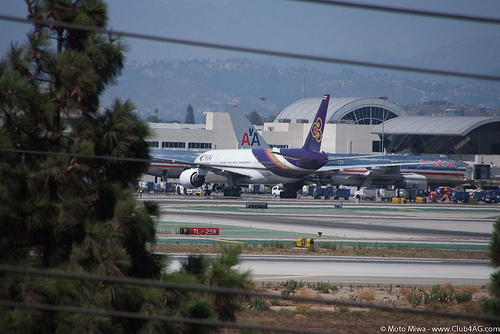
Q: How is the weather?
A: It is clear.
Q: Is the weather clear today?
A: Yes, it is clear.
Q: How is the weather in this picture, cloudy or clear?
A: It is clear.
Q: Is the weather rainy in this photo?
A: No, it is clear.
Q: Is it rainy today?
A: No, it is clear.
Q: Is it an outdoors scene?
A: Yes, it is outdoors.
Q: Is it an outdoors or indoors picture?
A: It is outdoors.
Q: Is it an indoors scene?
A: No, it is outdoors.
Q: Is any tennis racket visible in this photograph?
A: No, there are no rackets.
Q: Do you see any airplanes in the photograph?
A: Yes, there is an airplane.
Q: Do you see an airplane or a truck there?
A: Yes, there is an airplane.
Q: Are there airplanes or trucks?
A: Yes, there is an airplane.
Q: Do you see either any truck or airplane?
A: Yes, there is an airplane.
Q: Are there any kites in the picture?
A: No, there are no kites.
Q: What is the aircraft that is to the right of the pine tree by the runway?
A: The aircraft is an airplane.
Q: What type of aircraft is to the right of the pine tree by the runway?
A: The aircraft is an airplane.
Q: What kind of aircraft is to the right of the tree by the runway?
A: The aircraft is an airplane.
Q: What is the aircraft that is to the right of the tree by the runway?
A: The aircraft is an airplane.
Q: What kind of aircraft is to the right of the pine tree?
A: The aircraft is an airplane.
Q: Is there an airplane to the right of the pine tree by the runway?
A: Yes, there is an airplane to the right of the pine tree.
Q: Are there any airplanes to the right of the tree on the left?
A: Yes, there is an airplane to the right of the pine tree.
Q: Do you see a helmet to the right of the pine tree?
A: No, there is an airplane to the right of the pine tree.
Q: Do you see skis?
A: No, there are no skis.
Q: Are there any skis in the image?
A: No, there are no skis.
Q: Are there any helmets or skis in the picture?
A: No, there are no skis or helmets.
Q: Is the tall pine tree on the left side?
A: Yes, the pine tree is on the left of the image.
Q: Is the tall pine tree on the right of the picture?
A: No, the pine tree is on the left of the image.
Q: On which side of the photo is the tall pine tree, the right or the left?
A: The pine is on the left of the image.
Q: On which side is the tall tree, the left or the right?
A: The pine is on the left of the image.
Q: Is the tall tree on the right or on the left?
A: The pine is on the left of the image.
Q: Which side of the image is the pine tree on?
A: The pine tree is on the left of the image.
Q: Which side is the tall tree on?
A: The pine tree is on the left of the image.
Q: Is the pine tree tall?
A: Yes, the pine tree is tall.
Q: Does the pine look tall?
A: Yes, the pine is tall.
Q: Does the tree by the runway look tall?
A: Yes, the pine is tall.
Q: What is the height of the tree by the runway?
A: The pine tree is tall.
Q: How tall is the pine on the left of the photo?
A: The pine tree is tall.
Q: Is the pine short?
A: No, the pine is tall.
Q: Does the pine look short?
A: No, the pine is tall.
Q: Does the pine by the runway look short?
A: No, the pine is tall.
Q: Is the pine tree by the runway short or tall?
A: The pine is tall.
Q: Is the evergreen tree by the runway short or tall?
A: The pine is tall.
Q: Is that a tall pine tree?
A: Yes, that is a tall pine tree.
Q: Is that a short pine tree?
A: No, that is a tall pine tree.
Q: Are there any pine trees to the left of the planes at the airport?
A: Yes, there is a pine tree to the left of the airplanes.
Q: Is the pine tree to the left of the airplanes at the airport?
A: Yes, the pine tree is to the left of the airplanes.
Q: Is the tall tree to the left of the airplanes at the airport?
A: Yes, the pine tree is to the left of the airplanes.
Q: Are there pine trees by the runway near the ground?
A: Yes, there is a pine tree by the runway.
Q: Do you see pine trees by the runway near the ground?
A: Yes, there is a pine tree by the runway.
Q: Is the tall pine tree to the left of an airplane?
A: Yes, the pine is to the left of an airplane.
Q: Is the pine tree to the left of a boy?
A: No, the pine tree is to the left of an airplane.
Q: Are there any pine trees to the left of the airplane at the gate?
A: Yes, there is a pine tree to the left of the plane.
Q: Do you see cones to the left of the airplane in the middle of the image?
A: No, there is a pine tree to the left of the plane.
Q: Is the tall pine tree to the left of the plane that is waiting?
A: Yes, the pine tree is to the left of the plane.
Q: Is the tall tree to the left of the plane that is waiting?
A: Yes, the pine tree is to the left of the plane.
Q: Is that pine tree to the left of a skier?
A: No, the pine tree is to the left of the plane.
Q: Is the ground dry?
A: Yes, the ground is dry.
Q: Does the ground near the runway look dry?
A: Yes, the ground is dry.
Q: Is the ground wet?
A: No, the ground is dry.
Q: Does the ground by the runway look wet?
A: No, the ground is dry.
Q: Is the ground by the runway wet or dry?
A: The ground is dry.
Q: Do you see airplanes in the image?
A: Yes, there is an airplane.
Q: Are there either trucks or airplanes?
A: Yes, there is an airplane.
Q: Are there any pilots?
A: No, there are no pilots.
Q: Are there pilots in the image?
A: No, there are no pilots.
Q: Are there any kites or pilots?
A: No, there are no pilots or kites.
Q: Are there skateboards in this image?
A: No, there are no skateboards.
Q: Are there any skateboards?
A: No, there are no skateboards.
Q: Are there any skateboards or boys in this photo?
A: No, there are no skateboards or boys.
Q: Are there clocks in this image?
A: No, there are no clocks.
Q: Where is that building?
A: The building is at the airport.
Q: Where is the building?
A: The building is at the airport.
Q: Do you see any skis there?
A: No, there are no skis.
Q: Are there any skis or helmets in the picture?
A: No, there are no skis or helmets.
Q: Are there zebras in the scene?
A: No, there are no zebras.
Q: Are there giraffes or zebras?
A: No, there are no zebras or giraffes.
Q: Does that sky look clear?
A: Yes, the sky is clear.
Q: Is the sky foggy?
A: No, the sky is clear.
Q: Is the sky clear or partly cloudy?
A: The sky is clear.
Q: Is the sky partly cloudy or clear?
A: The sky is clear.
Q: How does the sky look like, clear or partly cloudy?
A: The sky is clear.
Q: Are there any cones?
A: No, there are no cones.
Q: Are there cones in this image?
A: No, there are no cones.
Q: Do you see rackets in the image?
A: No, there are no rackets.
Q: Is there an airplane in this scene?
A: Yes, there is an airplane.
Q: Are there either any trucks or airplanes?
A: Yes, there is an airplane.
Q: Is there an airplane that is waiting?
A: Yes, there is an airplane that is waiting.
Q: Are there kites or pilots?
A: No, there are no pilots or kites.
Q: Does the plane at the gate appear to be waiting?
A: Yes, the airplane is waiting.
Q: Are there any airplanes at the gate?
A: Yes, there is an airplane at the gate.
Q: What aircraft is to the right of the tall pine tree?
A: The aircraft is an airplane.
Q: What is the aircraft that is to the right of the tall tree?
A: The aircraft is an airplane.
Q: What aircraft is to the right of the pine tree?
A: The aircraft is an airplane.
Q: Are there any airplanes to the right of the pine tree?
A: Yes, there is an airplane to the right of the pine tree.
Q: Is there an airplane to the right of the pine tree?
A: Yes, there is an airplane to the right of the pine tree.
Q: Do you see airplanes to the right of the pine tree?
A: Yes, there is an airplane to the right of the pine tree.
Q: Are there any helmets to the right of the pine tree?
A: No, there is an airplane to the right of the pine tree.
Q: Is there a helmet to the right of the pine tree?
A: No, there is an airplane to the right of the pine tree.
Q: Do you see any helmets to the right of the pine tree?
A: No, there is an airplane to the right of the pine tree.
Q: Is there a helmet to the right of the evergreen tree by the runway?
A: No, there is an airplane to the right of the pine tree.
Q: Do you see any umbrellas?
A: No, there are no umbrellas.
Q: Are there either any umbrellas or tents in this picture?
A: No, there are no umbrellas or tents.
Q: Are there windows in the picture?
A: Yes, there is a window.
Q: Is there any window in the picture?
A: Yes, there is a window.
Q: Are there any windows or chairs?
A: Yes, there is a window.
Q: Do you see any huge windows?
A: Yes, there is a huge window.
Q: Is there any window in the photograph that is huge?
A: Yes, there is a window that is huge.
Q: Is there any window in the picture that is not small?
A: Yes, there is a huge window.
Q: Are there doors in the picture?
A: No, there are no doors.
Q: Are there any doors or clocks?
A: No, there are no doors or clocks.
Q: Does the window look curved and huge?
A: Yes, the window is curved and huge.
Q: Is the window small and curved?
A: No, the window is curved but huge.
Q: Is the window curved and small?
A: No, the window is curved but huge.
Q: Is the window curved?
A: Yes, the window is curved.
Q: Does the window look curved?
A: Yes, the window is curved.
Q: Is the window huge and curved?
A: Yes, the window is huge and curved.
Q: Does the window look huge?
A: Yes, the window is huge.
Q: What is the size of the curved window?
A: The window is huge.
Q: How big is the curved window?
A: The window is huge.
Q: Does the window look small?
A: No, the window is huge.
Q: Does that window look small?
A: No, the window is huge.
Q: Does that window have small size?
A: No, the window is huge.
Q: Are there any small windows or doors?
A: No, there is a window but it is huge.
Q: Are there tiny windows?
A: No, there is a window but it is huge.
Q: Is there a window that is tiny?
A: No, there is a window but it is huge.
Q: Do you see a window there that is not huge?
A: No, there is a window but it is huge.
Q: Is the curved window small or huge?
A: The window is huge.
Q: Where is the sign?
A: The sign is on the runway.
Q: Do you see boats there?
A: No, there are no boats.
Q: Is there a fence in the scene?
A: Yes, there is a fence.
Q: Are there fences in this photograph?
A: Yes, there is a fence.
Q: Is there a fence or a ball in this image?
A: Yes, there is a fence.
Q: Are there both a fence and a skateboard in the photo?
A: No, there is a fence but no skateboards.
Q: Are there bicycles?
A: No, there are no bicycles.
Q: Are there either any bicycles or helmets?
A: No, there are no bicycles or helmets.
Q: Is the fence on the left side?
A: Yes, the fence is on the left of the image.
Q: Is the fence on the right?
A: No, the fence is on the left of the image.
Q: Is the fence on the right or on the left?
A: The fence is on the left of the image.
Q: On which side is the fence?
A: The fence is on the left of the image.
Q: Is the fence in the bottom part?
A: Yes, the fence is in the bottom of the image.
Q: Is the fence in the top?
A: No, the fence is in the bottom of the image.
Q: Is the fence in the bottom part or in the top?
A: The fence is in the bottom of the image.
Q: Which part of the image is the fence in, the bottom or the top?
A: The fence is in the bottom of the image.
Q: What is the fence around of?
A: The fence is around the airport.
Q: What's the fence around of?
A: The fence is around the airport.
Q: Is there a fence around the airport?
A: Yes, there is a fence around the airport.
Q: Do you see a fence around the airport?
A: Yes, there is a fence around the airport.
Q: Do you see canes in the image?
A: No, there are no canes.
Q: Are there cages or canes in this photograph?
A: No, there are no canes or cages.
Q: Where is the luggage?
A: The luggage is on the runway.